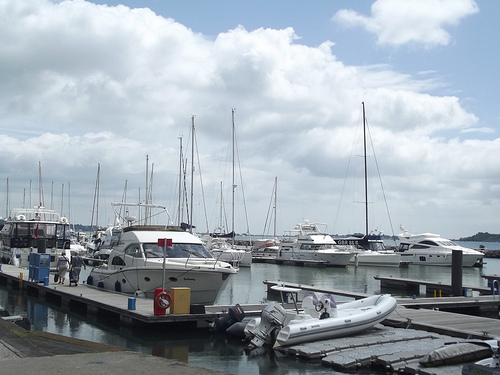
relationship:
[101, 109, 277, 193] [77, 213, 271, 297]
masts on boats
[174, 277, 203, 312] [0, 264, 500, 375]
box on marina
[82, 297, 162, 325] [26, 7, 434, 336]
birdges in photo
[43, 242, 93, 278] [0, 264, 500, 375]
people on marina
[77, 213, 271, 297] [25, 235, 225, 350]
boats in marina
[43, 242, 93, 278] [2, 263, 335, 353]
people on bridge